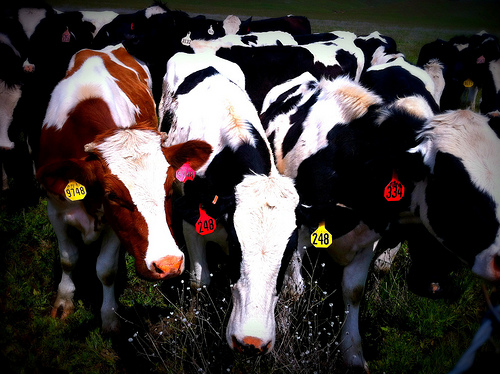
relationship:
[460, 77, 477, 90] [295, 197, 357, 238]
tag attached to ear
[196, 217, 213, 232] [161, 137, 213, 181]
248 attached to ear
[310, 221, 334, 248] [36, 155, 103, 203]
ear tag attached to ear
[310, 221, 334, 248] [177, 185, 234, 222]
ear tag attached to ear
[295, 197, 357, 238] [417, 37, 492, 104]
ear of cow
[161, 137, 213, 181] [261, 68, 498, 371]
ear of cow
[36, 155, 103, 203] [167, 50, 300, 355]
ear of cow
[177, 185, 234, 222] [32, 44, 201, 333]
ear of cow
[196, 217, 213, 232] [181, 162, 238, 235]
248 attached to ear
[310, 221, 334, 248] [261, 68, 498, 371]
ear tag attached to cow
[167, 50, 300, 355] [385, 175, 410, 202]
cow with tag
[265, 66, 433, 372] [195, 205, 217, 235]
cow with tag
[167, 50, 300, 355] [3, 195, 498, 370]
cow standing in grass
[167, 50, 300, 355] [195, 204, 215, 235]
cow with ear tag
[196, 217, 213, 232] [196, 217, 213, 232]
248 displaying 248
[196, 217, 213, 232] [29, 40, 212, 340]
248 on cow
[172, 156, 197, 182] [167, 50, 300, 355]
redtag on cow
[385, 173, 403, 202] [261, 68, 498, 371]
red tag on cow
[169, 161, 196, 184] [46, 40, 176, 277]
tag on cow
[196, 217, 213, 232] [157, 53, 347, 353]
248 on cow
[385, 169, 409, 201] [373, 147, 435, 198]
red tag in ear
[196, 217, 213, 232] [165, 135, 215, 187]
248 in ear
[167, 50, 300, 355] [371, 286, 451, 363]
cow standing in grass